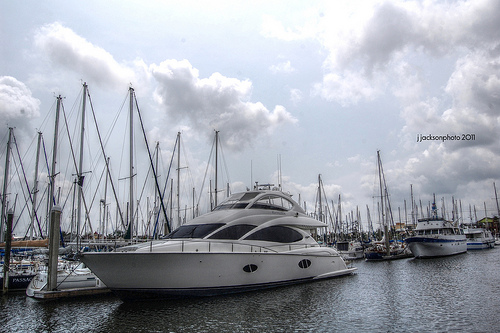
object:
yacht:
[73, 190, 358, 289]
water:
[0, 246, 499, 331]